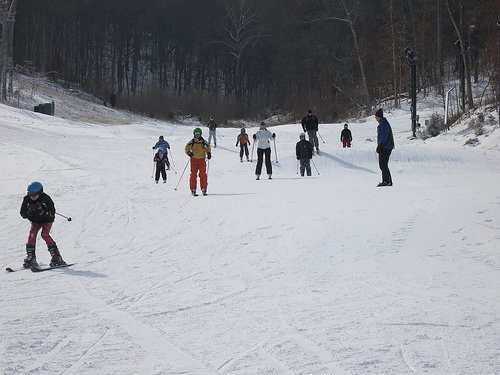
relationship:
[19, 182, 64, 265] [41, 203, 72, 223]
person holding pole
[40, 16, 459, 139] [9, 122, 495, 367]
forest behind field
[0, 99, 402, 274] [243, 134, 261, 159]
people holding poles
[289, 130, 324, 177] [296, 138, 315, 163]
person wearing jacket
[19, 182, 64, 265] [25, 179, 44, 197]
person wearing helmet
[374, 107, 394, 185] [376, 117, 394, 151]
man wearing jacket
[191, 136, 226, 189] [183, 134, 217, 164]
skier in coat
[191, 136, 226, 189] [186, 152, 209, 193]
skier in pants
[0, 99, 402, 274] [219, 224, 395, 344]
people on snow